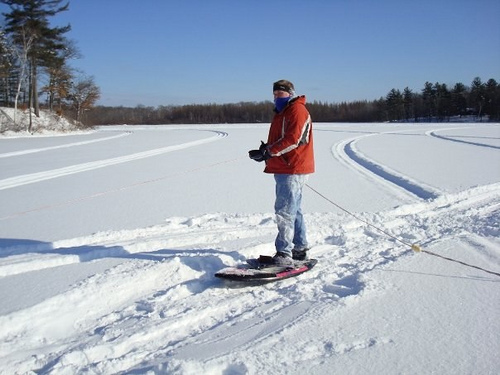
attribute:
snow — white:
[0, 109, 500, 372]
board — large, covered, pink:
[213, 253, 320, 284]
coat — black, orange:
[262, 92, 320, 173]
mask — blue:
[272, 95, 291, 116]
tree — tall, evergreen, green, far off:
[383, 89, 408, 126]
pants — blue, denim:
[268, 171, 309, 252]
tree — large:
[8, 5, 73, 115]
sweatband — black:
[272, 82, 294, 96]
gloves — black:
[249, 143, 271, 161]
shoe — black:
[271, 249, 297, 267]